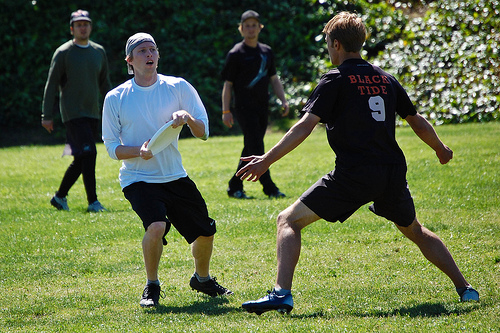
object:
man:
[234, 7, 482, 313]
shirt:
[303, 59, 418, 169]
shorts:
[296, 153, 415, 221]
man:
[225, 8, 287, 198]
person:
[37, 4, 116, 215]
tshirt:
[227, 43, 279, 107]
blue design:
[249, 55, 270, 88]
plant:
[389, 2, 495, 105]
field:
[4, 137, 497, 333]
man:
[101, 32, 237, 307]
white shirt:
[102, 75, 211, 188]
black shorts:
[123, 175, 224, 247]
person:
[221, 8, 291, 199]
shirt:
[40, 39, 108, 144]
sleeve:
[40, 46, 62, 121]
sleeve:
[100, 42, 113, 97]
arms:
[262, 76, 325, 167]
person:
[237, 11, 482, 311]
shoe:
[241, 291, 300, 315]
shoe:
[139, 284, 162, 308]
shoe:
[189, 275, 234, 298]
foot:
[241, 288, 295, 315]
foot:
[189, 273, 236, 298]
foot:
[139, 280, 159, 307]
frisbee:
[140, 115, 184, 157]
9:
[366, 95, 386, 122]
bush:
[279, 2, 499, 125]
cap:
[65, 5, 97, 27]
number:
[366, 95, 385, 122]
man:
[44, 7, 111, 212]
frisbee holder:
[97, 29, 229, 308]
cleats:
[246, 305, 294, 314]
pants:
[306, 154, 412, 223]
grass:
[1, 132, 500, 333]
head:
[68, 10, 93, 40]